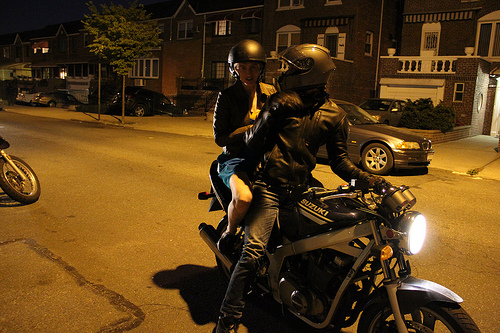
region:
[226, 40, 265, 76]
a black helmet on the passenger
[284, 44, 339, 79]
a black helmet on the driver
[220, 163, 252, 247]
the bare leg of the passenger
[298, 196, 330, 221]
the brand name of the motorcycle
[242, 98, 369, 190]
black leather jacket on the driver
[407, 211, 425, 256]
brightly lit headlight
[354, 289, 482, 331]
front tire of a motorcycle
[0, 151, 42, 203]
front tire of a second motorcycle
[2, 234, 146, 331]
black lined sqare on the street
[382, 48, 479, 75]
white wooden balcony on a house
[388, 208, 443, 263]
the headlight of a motorcycle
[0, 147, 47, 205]
the front wheel of a motorcycle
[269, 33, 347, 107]
a man wearing a motorcycle helmet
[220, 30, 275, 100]
a woman wearing a motorcycle helmet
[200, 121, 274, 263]
a woman wearing short pants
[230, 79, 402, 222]
a man wearing a leather jacket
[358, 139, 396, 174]
the right front wheel of a car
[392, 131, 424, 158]
the right front light of a car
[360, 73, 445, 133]
a car parked in front of a garage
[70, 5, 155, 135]
a tree on the side of a road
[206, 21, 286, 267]
a woman on the back of a motorcycle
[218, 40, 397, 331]
a man on the front of a motorcycle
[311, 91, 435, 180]
a blue bmw car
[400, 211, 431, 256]
a motorcycle headlight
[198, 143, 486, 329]
a suzuki brand motorcycle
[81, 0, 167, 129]
a small green tree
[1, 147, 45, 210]
a rubber motorcycle tire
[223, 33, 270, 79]
a black motorcycle helmet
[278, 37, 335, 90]
a grey motorcycle helmet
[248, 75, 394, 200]
a black leather jacket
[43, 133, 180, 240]
street for vehicles to travel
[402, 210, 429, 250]
light on the bike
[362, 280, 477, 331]
front tire on bike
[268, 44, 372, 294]
rider on the bike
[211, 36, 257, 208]
passenger behind the rider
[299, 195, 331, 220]
name on the bike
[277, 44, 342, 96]
helmet on biker's head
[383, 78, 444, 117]
garage in the unit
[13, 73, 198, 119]
vehicles along the street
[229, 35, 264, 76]
helmet on the passenger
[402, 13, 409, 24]
white stripe on building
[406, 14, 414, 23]
white stripe on building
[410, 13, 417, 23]
white stripe on building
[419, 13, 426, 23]
white stripe on building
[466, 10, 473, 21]
white stripe on building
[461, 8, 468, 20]
white stripe on building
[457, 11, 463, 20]
white stripe on building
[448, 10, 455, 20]
white stripe on building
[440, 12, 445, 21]
white stripe on building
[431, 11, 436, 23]
white stripe on building